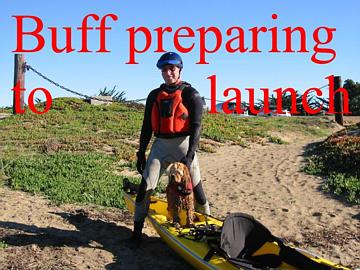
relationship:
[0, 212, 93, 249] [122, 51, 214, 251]
shadow of person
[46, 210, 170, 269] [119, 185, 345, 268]
shadow of kayak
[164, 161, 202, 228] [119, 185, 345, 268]
dog in kayak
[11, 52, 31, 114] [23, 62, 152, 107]
post with rope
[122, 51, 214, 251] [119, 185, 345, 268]
person with kayak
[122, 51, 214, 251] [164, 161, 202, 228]
person with dog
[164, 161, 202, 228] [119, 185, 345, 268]
dog on kayak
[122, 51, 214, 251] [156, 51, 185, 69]
person with helmet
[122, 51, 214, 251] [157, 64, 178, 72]
person with sunglasses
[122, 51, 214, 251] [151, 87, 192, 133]
person in life vest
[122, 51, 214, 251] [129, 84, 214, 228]
person in wet suit